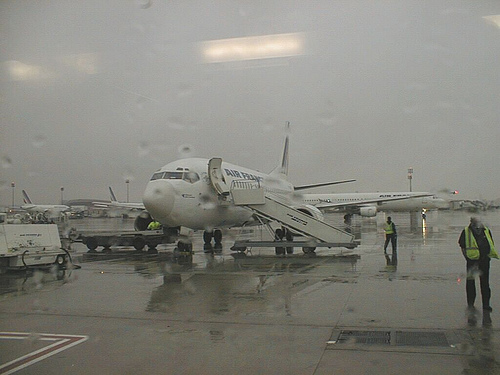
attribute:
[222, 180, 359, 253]
stairs — whire, mobile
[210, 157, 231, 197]
door — open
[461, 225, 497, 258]
vest — green, neon, bright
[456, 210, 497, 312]
person — crew, standing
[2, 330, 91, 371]
line — painted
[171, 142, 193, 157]
water — drop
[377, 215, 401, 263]
man — walking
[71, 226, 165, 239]
bed — flat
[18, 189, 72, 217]
jet — distant